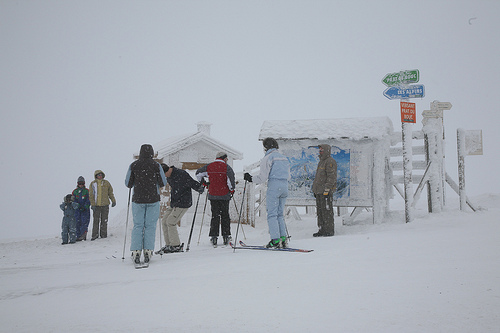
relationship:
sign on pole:
[382, 68, 418, 85] [402, 96, 411, 220]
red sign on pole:
[392, 99, 422, 129] [395, 105, 415, 225]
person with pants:
[243, 136, 291, 251] [263, 177, 293, 240]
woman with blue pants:
[239, 132, 299, 253] [269, 179, 291, 236]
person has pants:
[123, 143, 168, 269] [110, 182, 189, 272]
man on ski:
[244, 137, 292, 247] [227, 241, 312, 252]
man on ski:
[244, 137, 292, 247] [239, 240, 309, 249]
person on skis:
[123, 144, 165, 276] [119, 186, 132, 261]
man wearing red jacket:
[204, 164, 234, 237] [199, 162, 236, 217]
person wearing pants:
[243, 136, 291, 251] [262, 179, 292, 246]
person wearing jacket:
[243, 136, 291, 251] [251, 146, 291, 183]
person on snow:
[82, 167, 118, 242] [298, 262, 450, 323]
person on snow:
[61, 172, 94, 247] [298, 262, 450, 323]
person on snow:
[156, 161, 213, 259] [298, 262, 450, 323]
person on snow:
[241, 129, 291, 251] [298, 262, 450, 323]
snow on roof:
[3, 217, 498, 332] [265, 114, 387, 139]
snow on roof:
[276, 119, 391, 138] [265, 114, 387, 139]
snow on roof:
[158, 130, 193, 146] [265, 114, 387, 139]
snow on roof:
[158, 130, 193, 146] [154, 126, 240, 154]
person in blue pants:
[122, 144, 172, 261] [129, 204, 161, 254]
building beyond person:
[134, 122, 242, 226] [125, 140, 170, 266]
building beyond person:
[134, 122, 242, 226] [159, 165, 203, 251]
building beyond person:
[134, 122, 242, 226] [197, 152, 235, 244]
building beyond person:
[134, 122, 242, 226] [243, 137, 288, 247]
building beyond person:
[134, 122, 242, 226] [314, 144, 336, 235]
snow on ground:
[276, 119, 391, 138] [11, 193, 475, 330]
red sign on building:
[399, 100, 417, 122] [237, 102, 415, 233]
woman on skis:
[259, 135, 290, 249] [229, 231, 316, 257]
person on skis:
[195, 151, 236, 248] [193, 212, 311, 257]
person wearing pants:
[243, 136, 291, 251] [254, 188, 291, 252]